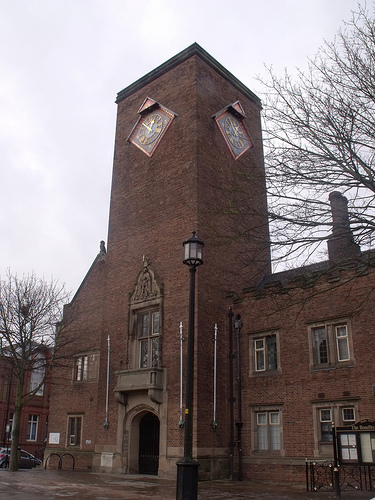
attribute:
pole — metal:
[174, 268, 203, 498]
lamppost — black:
[165, 227, 208, 490]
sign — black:
[334, 426, 373, 464]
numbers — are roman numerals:
[137, 113, 163, 144]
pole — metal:
[173, 266, 197, 498]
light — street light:
[182, 230, 204, 267]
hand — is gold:
[145, 117, 157, 133]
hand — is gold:
[139, 119, 151, 130]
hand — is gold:
[228, 117, 238, 136]